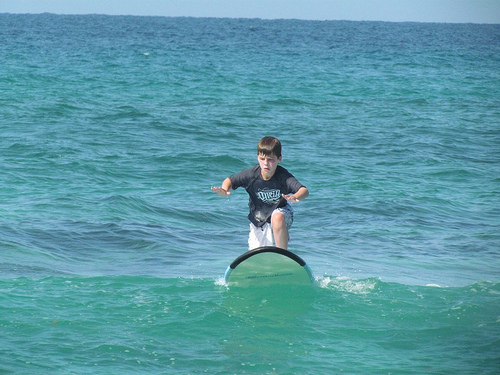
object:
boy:
[211, 134, 311, 252]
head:
[254, 135, 284, 173]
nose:
[263, 158, 269, 167]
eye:
[260, 155, 266, 163]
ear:
[275, 153, 284, 165]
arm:
[279, 167, 310, 208]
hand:
[281, 192, 300, 206]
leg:
[268, 204, 294, 253]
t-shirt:
[226, 166, 308, 230]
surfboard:
[222, 245, 319, 291]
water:
[1, 15, 499, 375]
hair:
[256, 134, 285, 159]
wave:
[2, 267, 499, 324]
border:
[228, 245, 312, 272]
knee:
[269, 209, 291, 227]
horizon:
[1, 9, 499, 33]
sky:
[3, 1, 500, 26]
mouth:
[262, 165, 273, 172]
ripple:
[87, 218, 163, 241]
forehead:
[256, 145, 284, 155]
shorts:
[246, 204, 293, 252]